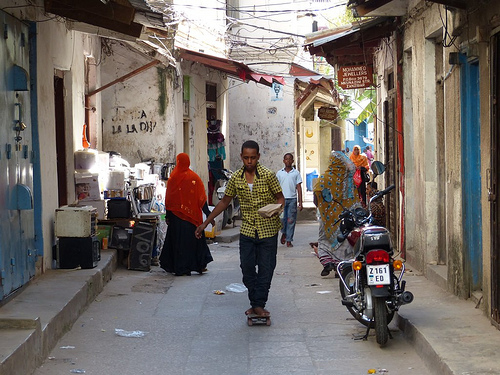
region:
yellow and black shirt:
[222, 161, 292, 243]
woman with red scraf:
[163, 149, 213, 231]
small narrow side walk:
[17, 259, 94, 334]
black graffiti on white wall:
[107, 106, 164, 147]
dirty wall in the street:
[251, 104, 291, 139]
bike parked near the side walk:
[316, 147, 436, 357]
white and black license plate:
[360, 259, 395, 293]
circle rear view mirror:
[318, 187, 343, 211]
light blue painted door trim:
[452, 99, 492, 309]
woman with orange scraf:
[347, 140, 371, 167]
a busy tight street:
[66, 75, 406, 317]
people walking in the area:
[150, 116, 404, 307]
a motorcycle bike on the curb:
[317, 186, 413, 339]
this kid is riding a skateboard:
[197, 138, 286, 325]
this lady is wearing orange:
[143, 142, 219, 281]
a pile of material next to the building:
[55, 141, 166, 281]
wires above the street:
[187, 5, 334, 59]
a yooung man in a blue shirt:
[273, 146, 308, 251]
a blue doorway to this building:
[438, 52, 488, 289]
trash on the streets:
[98, 268, 342, 343]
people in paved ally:
[164, 142, 371, 331]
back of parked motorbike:
[334, 162, 421, 346]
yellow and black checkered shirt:
[224, 167, 283, 241]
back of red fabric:
[164, 151, 206, 228]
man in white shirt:
[278, 152, 303, 202]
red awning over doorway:
[183, 49, 282, 118]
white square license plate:
[366, 262, 389, 286]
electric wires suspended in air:
[171, 0, 364, 59]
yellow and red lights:
[349, 248, 407, 273]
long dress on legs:
[156, 216, 212, 274]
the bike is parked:
[302, 167, 414, 365]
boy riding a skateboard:
[202, 114, 332, 322]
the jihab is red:
[150, 136, 211, 228]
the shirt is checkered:
[219, 162, 287, 258]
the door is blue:
[440, 55, 498, 333]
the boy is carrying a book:
[201, 124, 300, 327]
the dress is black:
[152, 196, 207, 276]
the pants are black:
[227, 219, 282, 316]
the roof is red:
[194, 46, 301, 98]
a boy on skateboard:
[187, 129, 287, 371]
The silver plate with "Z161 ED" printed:
[369, 263, 390, 283]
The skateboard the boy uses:
[240, 310, 275, 330]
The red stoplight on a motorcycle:
[363, 248, 390, 269]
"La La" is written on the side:
[101, 115, 140, 146]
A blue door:
[458, 57, 487, 304]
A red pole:
[396, 69, 406, 264]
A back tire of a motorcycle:
[365, 297, 394, 358]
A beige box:
[48, 204, 97, 244]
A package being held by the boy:
[255, 195, 285, 224]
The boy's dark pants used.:
[238, 228, 281, 310]